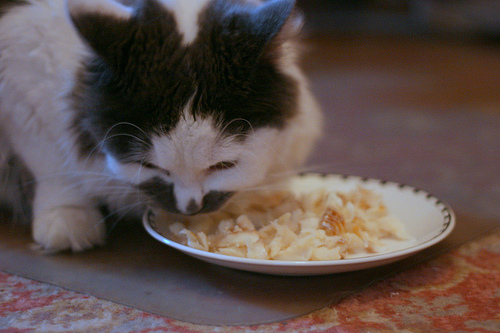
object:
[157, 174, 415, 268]
cat food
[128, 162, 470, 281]
plate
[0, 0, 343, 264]
cat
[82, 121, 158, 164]
whisker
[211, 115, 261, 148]
whisker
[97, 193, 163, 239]
whisker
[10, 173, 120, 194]
whisker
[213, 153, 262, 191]
whisker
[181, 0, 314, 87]
ear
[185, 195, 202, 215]
dot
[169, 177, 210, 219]
cat's nose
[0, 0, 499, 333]
carpet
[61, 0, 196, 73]
ear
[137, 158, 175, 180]
eye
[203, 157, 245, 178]
eye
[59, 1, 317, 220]
cat face